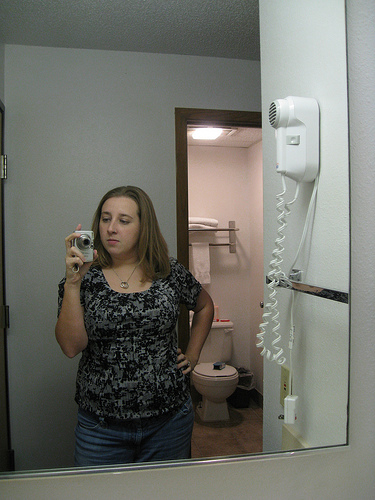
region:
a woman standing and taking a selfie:
[54, 187, 205, 463]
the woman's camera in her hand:
[74, 230, 92, 261]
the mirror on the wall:
[1, 0, 348, 478]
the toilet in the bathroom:
[186, 315, 241, 426]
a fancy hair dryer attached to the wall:
[252, 95, 322, 423]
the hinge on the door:
[0, 153, 9, 181]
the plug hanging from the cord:
[277, 394, 299, 425]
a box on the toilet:
[211, 358, 226, 368]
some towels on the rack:
[189, 214, 221, 285]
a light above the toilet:
[188, 126, 235, 142]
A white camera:
[61, 222, 90, 268]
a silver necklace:
[107, 259, 140, 289]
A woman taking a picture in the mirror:
[61, 175, 191, 452]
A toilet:
[195, 302, 253, 425]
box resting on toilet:
[206, 362, 234, 373]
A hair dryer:
[257, 80, 334, 208]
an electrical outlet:
[254, 369, 301, 417]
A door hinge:
[0, 135, 16, 200]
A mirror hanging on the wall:
[0, 7, 353, 467]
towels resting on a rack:
[189, 205, 246, 233]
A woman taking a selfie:
[46, 172, 226, 474]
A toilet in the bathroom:
[176, 301, 251, 429]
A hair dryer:
[252, 91, 322, 347]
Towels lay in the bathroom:
[168, 205, 237, 298]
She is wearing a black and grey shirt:
[40, 260, 200, 427]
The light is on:
[191, 117, 264, 191]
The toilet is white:
[180, 294, 257, 420]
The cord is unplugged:
[260, 356, 306, 428]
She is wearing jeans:
[4, 387, 212, 497]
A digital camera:
[56, 223, 98, 271]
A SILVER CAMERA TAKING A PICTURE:
[65, 223, 101, 277]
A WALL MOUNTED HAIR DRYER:
[248, 88, 332, 372]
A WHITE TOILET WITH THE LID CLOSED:
[184, 311, 244, 431]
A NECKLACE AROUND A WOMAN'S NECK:
[101, 252, 148, 288]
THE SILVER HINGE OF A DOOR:
[0, 149, 11, 183]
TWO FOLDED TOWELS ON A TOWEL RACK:
[181, 211, 222, 234]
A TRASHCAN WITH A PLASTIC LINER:
[229, 360, 261, 415]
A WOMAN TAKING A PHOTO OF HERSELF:
[44, 179, 212, 467]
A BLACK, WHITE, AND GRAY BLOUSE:
[53, 248, 208, 432]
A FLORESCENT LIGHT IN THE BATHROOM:
[190, 123, 230, 147]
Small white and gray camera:
[70, 229, 95, 261]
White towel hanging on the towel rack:
[193, 241, 213, 283]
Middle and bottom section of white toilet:
[191, 360, 237, 424]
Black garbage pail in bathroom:
[238, 366, 255, 406]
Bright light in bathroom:
[197, 128, 224, 140]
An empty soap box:
[211, 361, 224, 372]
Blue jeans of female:
[84, 429, 194, 461]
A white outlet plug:
[280, 394, 298, 426]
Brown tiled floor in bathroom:
[218, 434, 242, 452]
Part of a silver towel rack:
[217, 222, 237, 252]